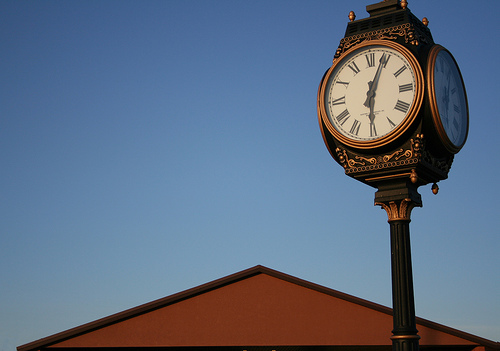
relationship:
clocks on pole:
[317, 42, 472, 156] [374, 176, 428, 350]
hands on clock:
[366, 50, 385, 133] [329, 43, 418, 149]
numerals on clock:
[380, 61, 415, 113] [329, 43, 418, 149]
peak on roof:
[248, 262, 271, 272] [19, 263, 389, 346]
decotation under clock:
[374, 197, 421, 221] [329, 43, 418, 149]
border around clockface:
[319, 39, 426, 153] [329, 43, 418, 149]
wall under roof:
[181, 304, 340, 338] [19, 263, 389, 346]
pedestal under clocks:
[376, 177, 424, 225] [317, 42, 472, 156]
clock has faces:
[329, 43, 418, 149] [317, 42, 472, 156]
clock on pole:
[316, 2, 467, 182] [374, 176, 428, 350]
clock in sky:
[329, 43, 418, 149] [81, 7, 279, 76]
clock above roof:
[329, 43, 418, 149] [19, 263, 389, 346]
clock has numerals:
[329, 43, 418, 149] [380, 61, 415, 113]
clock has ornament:
[329, 43, 418, 149] [374, 197, 421, 221]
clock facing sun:
[329, 43, 418, 149] [296, 34, 420, 168]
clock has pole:
[329, 43, 418, 149] [374, 176, 428, 350]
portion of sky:
[112, 7, 314, 102] [81, 7, 279, 76]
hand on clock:
[366, 96, 378, 130] [329, 43, 418, 149]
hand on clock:
[366, 53, 387, 101] [329, 43, 418, 149]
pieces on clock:
[409, 169, 441, 195] [329, 43, 418, 149]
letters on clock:
[354, 109, 388, 118] [329, 43, 418, 149]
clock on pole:
[329, 43, 418, 149] [374, 176, 428, 350]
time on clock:
[362, 50, 398, 138] [329, 43, 418, 149]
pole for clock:
[374, 176, 428, 350] [329, 43, 418, 149]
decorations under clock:
[409, 169, 441, 195] [329, 43, 418, 149]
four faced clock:
[316, 2, 467, 182] [329, 43, 418, 149]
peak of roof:
[248, 253, 271, 284] [19, 263, 389, 346]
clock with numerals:
[329, 43, 418, 149] [380, 61, 415, 113]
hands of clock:
[366, 50, 385, 133] [329, 43, 418, 149]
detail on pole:
[374, 197, 421, 221] [374, 176, 428, 350]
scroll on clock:
[343, 148, 417, 167] [329, 43, 418, 149]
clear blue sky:
[15, 9, 311, 151] [81, 7, 279, 76]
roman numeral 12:
[380, 61, 415, 113] [364, 52, 378, 76]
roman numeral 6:
[365, 122, 381, 137] [363, 114, 382, 142]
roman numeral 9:
[327, 89, 351, 111] [325, 95, 349, 110]